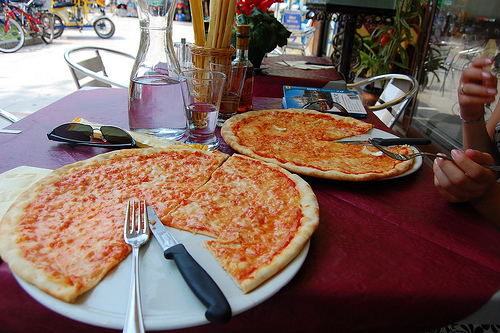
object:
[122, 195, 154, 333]
fork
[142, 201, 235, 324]
knife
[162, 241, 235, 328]
handle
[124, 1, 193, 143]
vase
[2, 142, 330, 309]
pizza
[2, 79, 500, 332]
table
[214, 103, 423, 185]
pizza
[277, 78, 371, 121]
book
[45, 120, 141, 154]
sunglasses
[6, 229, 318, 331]
plate